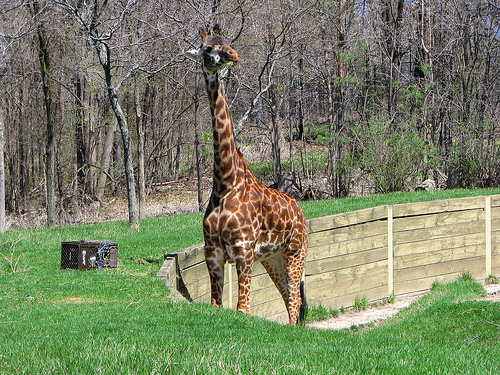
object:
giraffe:
[184, 22, 309, 327]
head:
[182, 23, 241, 73]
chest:
[202, 186, 247, 255]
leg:
[203, 244, 228, 309]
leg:
[258, 253, 290, 314]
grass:
[0, 188, 498, 375]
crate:
[59, 238, 119, 270]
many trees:
[25, 0, 75, 228]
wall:
[154, 195, 499, 314]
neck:
[204, 70, 261, 187]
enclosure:
[153, 194, 499, 308]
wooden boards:
[156, 255, 177, 292]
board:
[390, 195, 486, 219]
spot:
[213, 118, 222, 130]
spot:
[228, 136, 236, 155]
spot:
[210, 96, 226, 116]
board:
[390, 208, 485, 233]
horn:
[196, 28, 208, 42]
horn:
[210, 23, 222, 37]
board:
[391, 255, 486, 285]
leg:
[234, 252, 254, 316]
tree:
[64, 0, 141, 230]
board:
[391, 233, 485, 258]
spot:
[233, 167, 246, 188]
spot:
[217, 108, 225, 122]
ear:
[184, 48, 200, 59]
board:
[393, 267, 486, 299]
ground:
[301, 279, 499, 332]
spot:
[241, 225, 256, 243]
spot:
[228, 245, 243, 258]